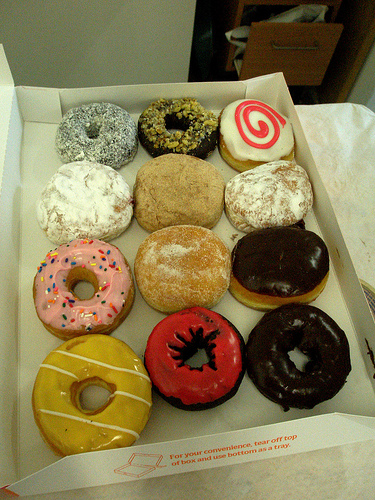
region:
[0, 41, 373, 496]
the box of donuts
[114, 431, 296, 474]
the instructions on the side of the box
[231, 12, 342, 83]
the drawer in the back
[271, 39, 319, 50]
the handle on the drawer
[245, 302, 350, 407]
the chocolate donut in the box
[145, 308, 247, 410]
the donut in the box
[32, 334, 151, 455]
the donut in the box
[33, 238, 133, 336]
the pink frosted donut in the box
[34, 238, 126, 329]
the sprinkles on the pink frosting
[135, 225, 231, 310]
the donut covered with sugar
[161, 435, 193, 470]
edge of a box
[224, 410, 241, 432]
part of a base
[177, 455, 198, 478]
part of a writing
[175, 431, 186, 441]
edge fo a box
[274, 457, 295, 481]
part of a surface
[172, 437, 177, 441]
edge of a box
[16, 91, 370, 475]
donuts in a cardboard box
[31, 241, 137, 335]
strawberry donut with sprinkles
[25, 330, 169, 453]
three white lines on the yellow donut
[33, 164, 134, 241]
donut covered in white powder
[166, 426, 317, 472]
orange writing on the side of the cardboard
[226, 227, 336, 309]
donut with chocolate frosting on top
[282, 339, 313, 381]
hole in the center of the donut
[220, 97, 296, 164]
pink swirl on the white donut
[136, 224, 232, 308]
donut with no hole in it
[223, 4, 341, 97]
drawer that is open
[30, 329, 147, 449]
yellow doughnut with white stripes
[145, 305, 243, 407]
chocolate doughnut with red frosting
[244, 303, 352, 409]
chocolate doughnut with chocolate frosting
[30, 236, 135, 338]
doughnut with pink frosting and rainbow sprinkles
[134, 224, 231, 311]
filled doughnut with powdered sugar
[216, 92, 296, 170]
filled doughnut with pink and white frosting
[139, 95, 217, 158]
chocolate doughnut with nuts on top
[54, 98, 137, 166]
chocolate doughnut with powdered sugar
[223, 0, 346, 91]
white plastic bag in brown wooden drawer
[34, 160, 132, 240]
filled doughnut with powdered sugar coating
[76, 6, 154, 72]
this is the wall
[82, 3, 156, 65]
the wall is white in color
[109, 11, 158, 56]
the wall is clean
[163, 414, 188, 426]
this is a box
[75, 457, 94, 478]
the box is white in color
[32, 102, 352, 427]
these are some doughnuts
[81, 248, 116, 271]
these are some sprinkles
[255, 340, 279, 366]
this is some cream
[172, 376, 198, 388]
the cream is red in color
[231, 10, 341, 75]
this is a drawer